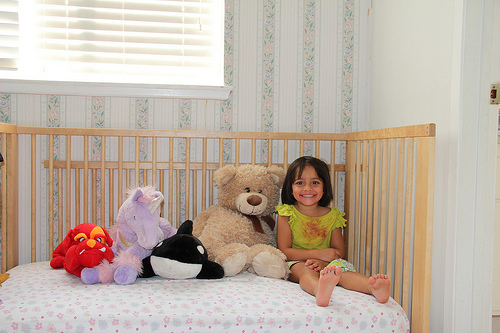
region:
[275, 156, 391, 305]
little girl sitting on a bed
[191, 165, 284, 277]
large brown teddy bear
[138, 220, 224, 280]
black and white whale on the bed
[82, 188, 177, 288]
purple unicorn on the bed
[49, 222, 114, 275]
red bulldog on the bed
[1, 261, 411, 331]
white mattress with pink flowers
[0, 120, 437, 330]
wooden head board and foot board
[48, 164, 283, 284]
collection of stuffed animals on the bed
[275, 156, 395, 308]
little girl sitting next to the stuffed animals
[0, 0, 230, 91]
window over the bed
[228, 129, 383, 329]
the girl is smiling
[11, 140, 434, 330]
toys beside the girl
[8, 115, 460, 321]
Little girl in a crib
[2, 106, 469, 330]
The crib is made of wood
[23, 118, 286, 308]
The crib has stuffed animals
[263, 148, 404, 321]
A little girl sitting in a crib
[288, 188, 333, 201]
The little girl is smiling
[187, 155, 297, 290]
The teddy bear is big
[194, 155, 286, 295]
The teddy bear is brown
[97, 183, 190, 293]
purple unicorn sitting in a crib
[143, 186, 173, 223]
Unicorn has a white horn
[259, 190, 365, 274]
Little girl wearing a yellow blouse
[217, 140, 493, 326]
The girl is in her bed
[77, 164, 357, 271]
Stuffed animals are in her bed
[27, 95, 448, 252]
Wallpaper is on the wall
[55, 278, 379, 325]
A floral sheet is on the bed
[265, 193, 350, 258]
A girl is wearing a green shirt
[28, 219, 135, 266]
The stuffed animal is red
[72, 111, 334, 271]
The bed is brown wood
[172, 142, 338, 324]
The bear is brown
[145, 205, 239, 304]
The dolphin is black and white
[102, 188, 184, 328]
The pony is purple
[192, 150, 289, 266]
a brown teddy bear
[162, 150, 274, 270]
a teddy bear on a bed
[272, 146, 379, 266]
a girl on a bed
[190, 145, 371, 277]
a girl with a teddy bear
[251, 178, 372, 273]
a girl with a yellow shirt on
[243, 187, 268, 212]
the brown nose of a teddy bear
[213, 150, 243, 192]
the ear of a teddy bear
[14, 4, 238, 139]
a window in a room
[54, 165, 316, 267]
stuffed animals on a bed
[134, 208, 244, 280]
a stuffed whale on a bed